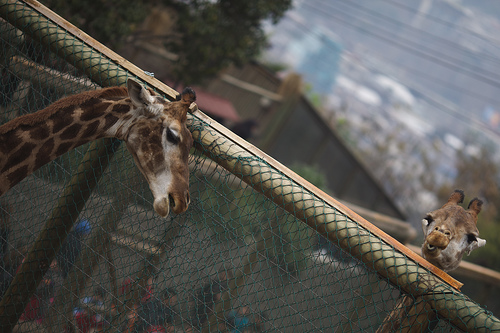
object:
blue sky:
[259, 0, 499, 232]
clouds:
[253, 0, 500, 234]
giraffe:
[0, 84, 197, 220]